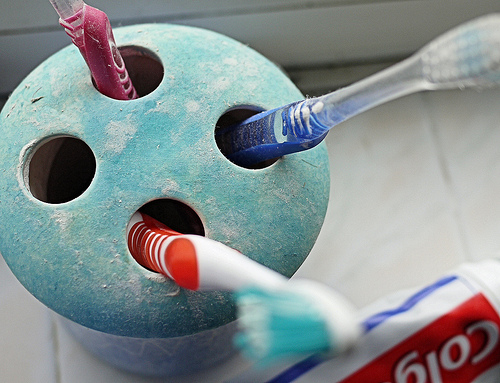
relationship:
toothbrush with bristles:
[121, 212, 353, 366] [232, 284, 330, 369]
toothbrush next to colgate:
[121, 212, 353, 366] [260, 260, 500, 383]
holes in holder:
[20, 133, 97, 205] [0, 23, 331, 377]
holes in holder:
[213, 104, 278, 171] [0, 23, 331, 377]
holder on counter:
[0, 23, 331, 377] [0, 56, 499, 381]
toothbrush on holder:
[126, 210, 358, 366] [87, 112, 245, 227]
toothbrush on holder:
[233, 10, 495, 159] [4, 19, 335, 348]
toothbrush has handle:
[233, 10, 495, 159] [230, 90, 331, 152]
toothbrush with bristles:
[121, 212, 353, 366] [228, 285, 330, 369]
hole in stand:
[13, 124, 105, 214] [4, 49, 348, 383]